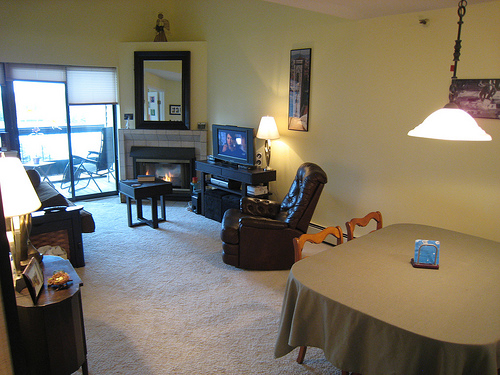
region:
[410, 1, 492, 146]
Hanging light above the table.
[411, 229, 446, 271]
Napkin holder in the center of the table.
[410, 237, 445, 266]
Blue and white napkin in the napkin holder.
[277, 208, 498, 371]
The table cloth on the table.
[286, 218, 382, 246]
Top pieces of the wooden chairs at the table.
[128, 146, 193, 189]
Center portion of the fireplace where the flames are seen.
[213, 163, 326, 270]
Leather recliner to the right of the television.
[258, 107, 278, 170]
Lamp next to the television.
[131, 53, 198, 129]
Black framed mirror above the fireplace.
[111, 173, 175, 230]
Small black center table in front of the television.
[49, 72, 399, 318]
small living room with sunny deck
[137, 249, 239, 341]
tan carpeting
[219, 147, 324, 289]
brown padded recliner chair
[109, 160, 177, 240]
small black table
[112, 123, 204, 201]
fire place with fire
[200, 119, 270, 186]
television on table is turned on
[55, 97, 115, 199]
lounge chair outside on sunny deck or patio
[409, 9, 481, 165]
white lamp hanging over table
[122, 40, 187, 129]
large mirror with dark brown trim over fireplace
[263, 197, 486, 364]
small table with light brown cloth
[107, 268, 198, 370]
carpet is grey color.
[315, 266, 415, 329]
table cloth is brown color.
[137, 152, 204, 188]
fire place is in the corner of the room.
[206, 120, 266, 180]
TV is black color.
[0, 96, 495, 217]
Three lamps are seen.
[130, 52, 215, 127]
Mirror is hanging in the wall.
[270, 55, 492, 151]
pictures are hanging in the wall.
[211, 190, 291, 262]
sofa is brown color.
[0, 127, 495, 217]
lights are on.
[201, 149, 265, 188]
TV is in the table.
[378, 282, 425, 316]
part of a brown cloth on the table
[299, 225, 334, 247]
part of a wooden table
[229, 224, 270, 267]
side of a sofa set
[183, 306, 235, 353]
part of white carpet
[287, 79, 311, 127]
part of a portrait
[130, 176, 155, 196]
part of a small table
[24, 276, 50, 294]
part of a picture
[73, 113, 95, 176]
part of a glassy door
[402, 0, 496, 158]
Hanging light with glass shade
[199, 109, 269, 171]
Black television with screen turned on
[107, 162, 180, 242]
Black coffee table with book on top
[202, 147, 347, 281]
Black leather reclining chair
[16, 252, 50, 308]
Small picture inside a frame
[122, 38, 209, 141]
Large mirror with black frame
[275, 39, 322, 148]
Mirror hanging on a wall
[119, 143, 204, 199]
Fireplace with fire burning inside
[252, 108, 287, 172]
Table lamp with shade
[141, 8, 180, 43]
Small decorative item